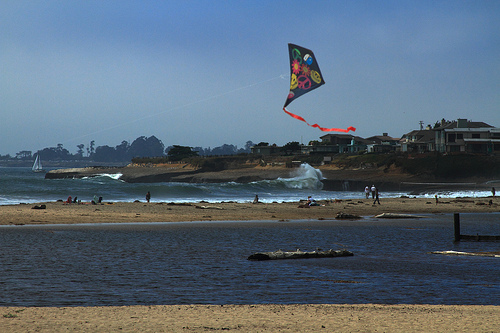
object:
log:
[248, 250, 355, 261]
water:
[1, 224, 500, 305]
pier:
[45, 167, 119, 178]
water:
[0, 183, 498, 200]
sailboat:
[32, 154, 43, 172]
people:
[365, 185, 370, 199]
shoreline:
[0, 196, 500, 223]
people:
[68, 197, 72, 205]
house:
[319, 134, 355, 144]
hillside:
[46, 152, 500, 191]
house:
[365, 135, 392, 144]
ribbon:
[283, 108, 356, 132]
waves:
[280, 164, 324, 189]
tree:
[283, 141, 300, 149]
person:
[491, 187, 495, 196]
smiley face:
[310, 70, 321, 84]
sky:
[0, 0, 497, 121]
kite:
[283, 43, 356, 133]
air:
[18, 6, 266, 131]